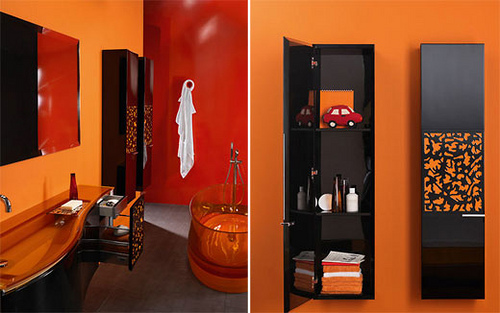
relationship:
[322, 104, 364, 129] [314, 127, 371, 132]
toy on shelf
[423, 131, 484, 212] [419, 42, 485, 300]
pattern on cabinet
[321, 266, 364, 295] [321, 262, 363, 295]
washcloths in stack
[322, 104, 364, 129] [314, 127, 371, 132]
car on shelf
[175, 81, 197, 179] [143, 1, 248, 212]
towel on wall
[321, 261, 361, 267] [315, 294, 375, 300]
book on shelf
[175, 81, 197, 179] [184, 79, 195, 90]
towel on ring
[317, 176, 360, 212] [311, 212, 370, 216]
toiletries on shelf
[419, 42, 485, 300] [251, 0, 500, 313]
shelving unit on wall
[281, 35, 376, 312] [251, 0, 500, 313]
shelving unit on wall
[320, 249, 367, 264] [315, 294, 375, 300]
papers on shelf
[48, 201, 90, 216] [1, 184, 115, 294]
dish on counter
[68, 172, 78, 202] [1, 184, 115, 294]
bottle on counter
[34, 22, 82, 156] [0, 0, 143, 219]
mirror on wall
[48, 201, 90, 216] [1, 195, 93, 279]
soap dish on sink